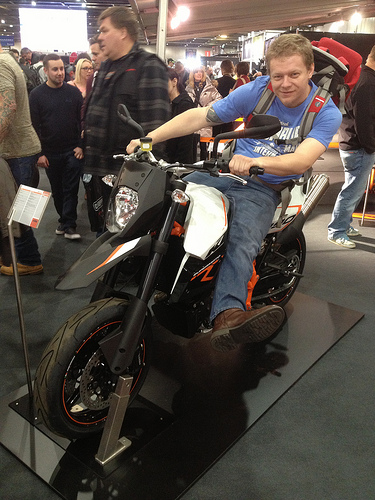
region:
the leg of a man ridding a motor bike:
[222, 181, 300, 363]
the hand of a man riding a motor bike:
[212, 154, 340, 176]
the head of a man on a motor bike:
[260, 24, 313, 108]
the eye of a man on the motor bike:
[292, 68, 301, 77]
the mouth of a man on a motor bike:
[278, 86, 304, 99]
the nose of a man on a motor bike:
[282, 76, 293, 93]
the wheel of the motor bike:
[28, 298, 161, 422]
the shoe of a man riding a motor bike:
[205, 299, 299, 347]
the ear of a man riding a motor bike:
[305, 59, 317, 78]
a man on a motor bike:
[156, 29, 329, 319]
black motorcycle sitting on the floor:
[31, 217, 306, 439]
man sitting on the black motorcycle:
[122, 35, 338, 351]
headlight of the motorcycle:
[112, 182, 135, 223]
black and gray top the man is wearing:
[85, 45, 168, 176]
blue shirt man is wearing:
[210, 72, 338, 187]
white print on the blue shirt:
[250, 122, 299, 157]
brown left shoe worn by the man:
[208, 301, 284, 357]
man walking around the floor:
[0, 24, 41, 274]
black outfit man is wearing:
[28, 83, 84, 233]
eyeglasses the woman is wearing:
[76, 63, 94, 73]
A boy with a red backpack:
[126, 33, 362, 350]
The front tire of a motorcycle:
[29, 295, 152, 439]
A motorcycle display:
[1, 102, 365, 497]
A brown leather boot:
[210, 303, 284, 353]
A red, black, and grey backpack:
[244, 34, 363, 147]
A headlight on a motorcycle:
[112, 185, 140, 228]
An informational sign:
[5, 182, 52, 229]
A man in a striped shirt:
[82, 5, 170, 238]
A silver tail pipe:
[301, 172, 330, 220]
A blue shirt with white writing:
[212, 73, 341, 184]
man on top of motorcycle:
[49, 36, 365, 411]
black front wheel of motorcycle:
[3, 297, 149, 462]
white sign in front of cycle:
[0, 188, 53, 226]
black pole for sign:
[3, 224, 45, 420]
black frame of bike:
[126, 210, 179, 338]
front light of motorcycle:
[115, 192, 137, 223]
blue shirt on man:
[219, 80, 333, 175]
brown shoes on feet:
[207, 296, 284, 350]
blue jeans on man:
[175, 186, 266, 318]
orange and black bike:
[190, 258, 223, 284]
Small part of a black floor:
[233, 448, 276, 470]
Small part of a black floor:
[257, 420, 287, 449]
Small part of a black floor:
[263, 466, 295, 491]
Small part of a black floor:
[292, 463, 318, 495]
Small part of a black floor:
[297, 415, 333, 464]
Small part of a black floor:
[329, 456, 369, 491]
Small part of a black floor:
[316, 402, 347, 440]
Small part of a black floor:
[325, 362, 365, 394]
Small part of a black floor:
[329, 250, 359, 290]